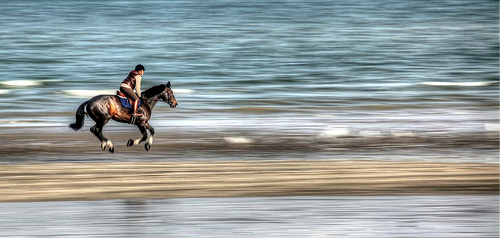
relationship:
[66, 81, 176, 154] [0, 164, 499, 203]
horse on sandbar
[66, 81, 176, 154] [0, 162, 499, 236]
horse off ground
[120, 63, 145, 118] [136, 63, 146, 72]
rider has on helmet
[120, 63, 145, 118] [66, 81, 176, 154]
rider on horse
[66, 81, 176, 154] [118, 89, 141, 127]
horse wearing saddle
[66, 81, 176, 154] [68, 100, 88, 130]
horse has tail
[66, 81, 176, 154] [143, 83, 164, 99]
horse has mane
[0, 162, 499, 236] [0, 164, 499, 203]
beach has sandbar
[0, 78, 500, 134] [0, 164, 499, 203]
waves hitting beach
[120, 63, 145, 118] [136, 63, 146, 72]
rider wearing helmet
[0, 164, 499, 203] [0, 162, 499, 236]
sandbar on beach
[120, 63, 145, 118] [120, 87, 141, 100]
rider wearing pants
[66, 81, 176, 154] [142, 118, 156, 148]
horse has legs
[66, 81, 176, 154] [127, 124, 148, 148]
horse has legs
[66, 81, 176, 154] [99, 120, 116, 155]
horse has legs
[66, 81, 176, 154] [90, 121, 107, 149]
horse has legs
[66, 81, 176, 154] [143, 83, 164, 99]
horse has a mane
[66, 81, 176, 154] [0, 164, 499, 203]
horse running on sandbar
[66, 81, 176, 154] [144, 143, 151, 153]
horse has feet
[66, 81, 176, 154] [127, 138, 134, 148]
horse has feet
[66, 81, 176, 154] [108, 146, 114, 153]
horse has feet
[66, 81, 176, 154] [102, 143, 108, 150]
horse has feet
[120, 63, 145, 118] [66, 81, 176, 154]
rider leaning on horse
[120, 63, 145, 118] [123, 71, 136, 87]
rider wearing vest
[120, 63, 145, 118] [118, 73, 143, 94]
rider wearing shirt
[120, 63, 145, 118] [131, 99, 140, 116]
rider wearing boots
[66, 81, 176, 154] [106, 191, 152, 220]
horse has reflection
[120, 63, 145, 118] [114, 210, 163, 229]
rider has reflection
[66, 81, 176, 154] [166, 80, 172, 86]
horse has ear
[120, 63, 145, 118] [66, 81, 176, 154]
rider on a horse